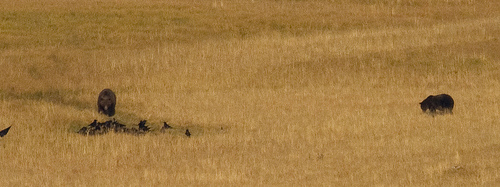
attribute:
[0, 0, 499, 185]
field — tan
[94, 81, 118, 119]
bear — large, brown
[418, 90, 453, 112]
bear — large, brown